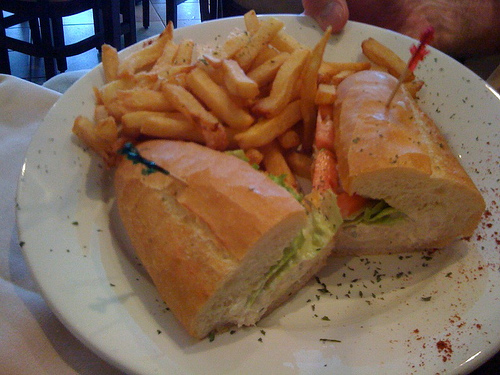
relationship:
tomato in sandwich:
[307, 99, 365, 215] [300, 63, 496, 259]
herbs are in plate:
[316, 248, 441, 327] [27, 19, 490, 369]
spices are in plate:
[442, 82, 495, 157] [27, 19, 490, 369]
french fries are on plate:
[75, 10, 436, 182] [27, 19, 490, 369]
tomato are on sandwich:
[307, 99, 365, 215] [115, 44, 488, 344]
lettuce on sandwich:
[243, 142, 409, 291] [106, 47, 476, 319]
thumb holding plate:
[300, 0, 330, 52] [27, 19, 490, 369]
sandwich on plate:
[116, 117, 337, 330] [27, 19, 490, 369]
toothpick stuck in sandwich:
[114, 131, 194, 181] [77, 137, 342, 327]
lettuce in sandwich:
[243, 142, 409, 291] [106, 47, 476, 319]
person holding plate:
[319, 11, 498, 29] [27, 19, 490, 369]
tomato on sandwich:
[307, 99, 365, 215] [297, 38, 497, 302]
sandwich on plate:
[309, 67, 487, 261] [27, 19, 490, 369]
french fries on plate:
[75, 10, 436, 182] [27, 19, 490, 369]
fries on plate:
[79, 14, 435, 150] [27, 19, 490, 369]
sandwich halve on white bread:
[116, 117, 337, 330] [112, 145, 299, 375]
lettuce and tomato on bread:
[243, 142, 409, 291] [137, 156, 234, 306]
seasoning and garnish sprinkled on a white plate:
[272, 212, 499, 362] [107, 292, 487, 375]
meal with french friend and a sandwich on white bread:
[114, 68, 465, 303] [155, 225, 253, 325]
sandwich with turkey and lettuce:
[116, 117, 337, 330] [254, 232, 316, 350]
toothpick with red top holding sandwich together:
[393, 51, 423, 90] [363, 118, 453, 288]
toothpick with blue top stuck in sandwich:
[114, 138, 171, 177] [137, 145, 292, 375]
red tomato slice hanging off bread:
[302, 103, 331, 220] [336, 152, 422, 283]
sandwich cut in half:
[135, 97, 450, 333] [277, 155, 373, 348]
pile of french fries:
[72, 99, 244, 159] [100, 52, 332, 131]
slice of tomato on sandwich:
[315, 100, 345, 205] [315, 56, 466, 256]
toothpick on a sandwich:
[114, 138, 171, 177] [122, 212, 254, 350]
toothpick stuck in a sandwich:
[392, 99, 418, 146] [342, 95, 432, 226]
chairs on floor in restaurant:
[10, 50, 71, 83] [1, 101, 45, 147]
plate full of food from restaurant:
[130, 260, 480, 375] [6, 51, 75, 186]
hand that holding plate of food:
[327, 50, 445, 61] [94, 115, 418, 288]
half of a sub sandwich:
[166, 195, 273, 352] [134, 179, 286, 298]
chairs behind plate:
[0, 3, 180, 76] [27, 19, 490, 369]